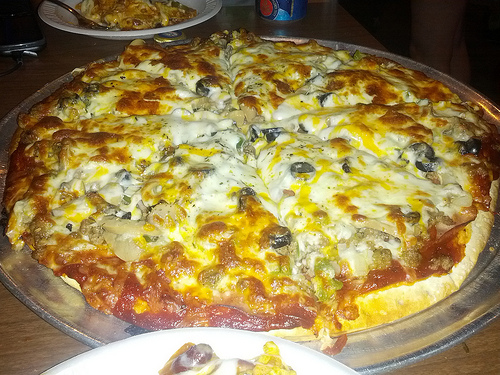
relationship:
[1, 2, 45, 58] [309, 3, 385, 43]
phone laying on table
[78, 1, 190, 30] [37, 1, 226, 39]
slice of pizza on a plate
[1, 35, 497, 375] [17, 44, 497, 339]
tray with food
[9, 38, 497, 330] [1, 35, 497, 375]
pizza on top of tray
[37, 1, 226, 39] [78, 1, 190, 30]
dinner plate with food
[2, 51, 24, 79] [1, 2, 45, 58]
wire charging phone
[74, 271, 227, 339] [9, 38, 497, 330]
crust of pizza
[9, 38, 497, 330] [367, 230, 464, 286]
pizza with sauce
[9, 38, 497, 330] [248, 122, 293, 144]
pizza with olives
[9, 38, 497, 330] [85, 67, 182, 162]
pizza with cheese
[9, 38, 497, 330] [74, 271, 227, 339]
pizza with crust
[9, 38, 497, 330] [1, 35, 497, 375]
pizza on tray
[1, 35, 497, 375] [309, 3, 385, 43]
tray on table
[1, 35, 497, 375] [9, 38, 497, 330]
tray of pizza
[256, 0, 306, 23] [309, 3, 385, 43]
can on table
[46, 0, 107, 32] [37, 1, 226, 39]
fork sitting on plate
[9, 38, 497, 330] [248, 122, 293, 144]
pizza has olives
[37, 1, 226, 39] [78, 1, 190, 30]
plate with pizza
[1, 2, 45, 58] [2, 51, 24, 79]
phone plugged into charger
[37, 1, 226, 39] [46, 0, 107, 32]
bowl with fork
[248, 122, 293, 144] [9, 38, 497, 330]
olives are on pizza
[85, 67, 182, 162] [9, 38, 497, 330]
cheese on pizza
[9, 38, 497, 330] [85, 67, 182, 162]
pizza has cheese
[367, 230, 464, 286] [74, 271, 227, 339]
sauce on crust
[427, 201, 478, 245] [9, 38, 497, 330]
sausage on pizza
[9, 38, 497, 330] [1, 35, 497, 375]
pizza on pie pan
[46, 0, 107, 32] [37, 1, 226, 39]
fork on bowl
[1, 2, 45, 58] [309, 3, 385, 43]
phone on table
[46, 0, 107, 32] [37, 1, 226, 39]
fork laying on plate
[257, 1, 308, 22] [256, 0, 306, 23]
bottom part of can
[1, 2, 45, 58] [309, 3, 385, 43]
phone laying on top of table